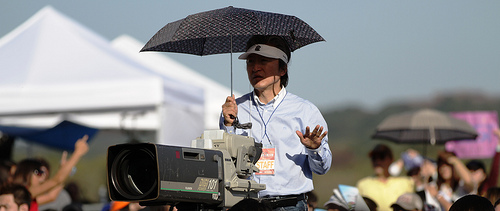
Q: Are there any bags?
A: No, there are no bags.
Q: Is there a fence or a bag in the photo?
A: No, there are no bags or fences.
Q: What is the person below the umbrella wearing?
A: The person is wearing a shirt.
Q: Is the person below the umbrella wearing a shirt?
A: Yes, the person is wearing a shirt.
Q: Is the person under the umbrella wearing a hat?
A: No, the person is wearing a shirt.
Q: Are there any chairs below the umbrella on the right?
A: No, there is a person below the umbrella.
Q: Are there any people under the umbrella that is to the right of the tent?
A: Yes, there is a person under the umbrella.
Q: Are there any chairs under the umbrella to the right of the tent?
A: No, there is a person under the umbrella.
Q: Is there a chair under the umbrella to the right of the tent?
A: No, there is a person under the umbrella.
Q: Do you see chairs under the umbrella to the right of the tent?
A: No, there is a person under the umbrella.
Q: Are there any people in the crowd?
A: Yes, there is a person in the crowd.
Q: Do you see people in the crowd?
A: Yes, there is a person in the crowd.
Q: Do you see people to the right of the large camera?
A: Yes, there is a person to the right of the camera.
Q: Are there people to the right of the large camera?
A: Yes, there is a person to the right of the camera.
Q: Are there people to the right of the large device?
A: Yes, there is a person to the right of the camera.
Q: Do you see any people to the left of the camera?
A: No, the person is to the right of the camera.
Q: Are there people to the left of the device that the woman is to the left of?
A: No, the person is to the right of the camera.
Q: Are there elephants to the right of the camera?
A: No, there is a person to the right of the camera.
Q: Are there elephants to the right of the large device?
A: No, there is a person to the right of the camera.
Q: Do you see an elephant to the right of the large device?
A: No, there is a person to the right of the camera.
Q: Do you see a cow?
A: No, there are no cows.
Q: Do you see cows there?
A: No, there are no cows.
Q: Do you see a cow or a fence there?
A: No, there are no cows or fences.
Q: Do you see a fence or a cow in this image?
A: No, there are no cows or fences.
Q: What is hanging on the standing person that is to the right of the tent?
A: The tag is hanging on the person.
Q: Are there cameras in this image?
A: Yes, there is a camera.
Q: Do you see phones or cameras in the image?
A: Yes, there is a camera.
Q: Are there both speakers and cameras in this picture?
A: No, there is a camera but no speakers.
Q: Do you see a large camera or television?
A: Yes, there is a large camera.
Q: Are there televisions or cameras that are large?
A: Yes, the camera is large.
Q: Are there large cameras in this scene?
A: Yes, there is a large camera.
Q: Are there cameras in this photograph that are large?
A: Yes, there is a camera that is large.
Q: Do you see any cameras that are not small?
A: Yes, there is a large camera.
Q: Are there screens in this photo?
A: No, there are no screens.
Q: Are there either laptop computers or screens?
A: No, there are no screens or laptop computers.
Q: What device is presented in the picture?
A: The device is a camera.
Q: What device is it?
A: The device is a camera.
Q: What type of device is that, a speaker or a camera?
A: This is a camera.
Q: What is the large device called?
A: The device is a camera.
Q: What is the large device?
A: The device is a camera.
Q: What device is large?
A: The device is a camera.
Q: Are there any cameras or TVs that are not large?
A: No, there is a camera but it is large.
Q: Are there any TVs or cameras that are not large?
A: No, there is a camera but it is large.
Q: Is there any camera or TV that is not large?
A: No, there is a camera but it is large.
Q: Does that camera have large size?
A: Yes, the camera is large.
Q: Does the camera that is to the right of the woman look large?
A: Yes, the camera is large.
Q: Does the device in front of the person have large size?
A: Yes, the camera is large.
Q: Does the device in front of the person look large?
A: Yes, the camera is large.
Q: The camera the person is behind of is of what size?
A: The camera is large.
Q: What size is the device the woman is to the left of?
A: The camera is large.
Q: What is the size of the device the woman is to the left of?
A: The camera is large.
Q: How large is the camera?
A: The camera is large.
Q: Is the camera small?
A: No, the camera is large.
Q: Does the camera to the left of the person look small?
A: No, the camera is large.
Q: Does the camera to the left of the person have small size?
A: No, the camera is large.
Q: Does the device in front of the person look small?
A: No, the camera is large.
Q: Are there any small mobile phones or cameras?
A: No, there is a camera but it is large.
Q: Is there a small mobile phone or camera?
A: No, there is a camera but it is large.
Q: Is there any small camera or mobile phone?
A: No, there is a camera but it is large.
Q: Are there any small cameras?
A: No, there is a camera but it is large.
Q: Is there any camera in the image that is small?
A: No, there is a camera but it is large.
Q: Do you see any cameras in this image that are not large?
A: No, there is a camera but it is large.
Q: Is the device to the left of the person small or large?
A: The camera is large.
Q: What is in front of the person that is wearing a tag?
A: The camera is in front of the person.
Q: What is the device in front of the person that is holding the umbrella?
A: The device is a camera.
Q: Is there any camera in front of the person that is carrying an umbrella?
A: Yes, there is a camera in front of the person.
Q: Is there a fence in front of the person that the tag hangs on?
A: No, there is a camera in front of the person.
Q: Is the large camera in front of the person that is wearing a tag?
A: Yes, the camera is in front of the person.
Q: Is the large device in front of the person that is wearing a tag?
A: Yes, the camera is in front of the person.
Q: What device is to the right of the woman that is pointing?
A: The device is a camera.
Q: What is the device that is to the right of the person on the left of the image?
A: The device is a camera.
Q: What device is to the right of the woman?
A: The device is a camera.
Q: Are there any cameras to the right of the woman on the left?
A: Yes, there is a camera to the right of the woman.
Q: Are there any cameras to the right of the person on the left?
A: Yes, there is a camera to the right of the woman.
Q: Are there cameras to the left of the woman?
A: No, the camera is to the right of the woman.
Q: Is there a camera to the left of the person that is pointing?
A: No, the camera is to the right of the woman.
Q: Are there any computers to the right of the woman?
A: No, there is a camera to the right of the woman.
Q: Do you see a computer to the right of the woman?
A: No, there is a camera to the right of the woman.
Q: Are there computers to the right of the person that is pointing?
A: No, there is a camera to the right of the woman.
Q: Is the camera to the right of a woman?
A: Yes, the camera is to the right of a woman.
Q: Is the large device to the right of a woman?
A: Yes, the camera is to the right of a woman.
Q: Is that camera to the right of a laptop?
A: No, the camera is to the right of a woman.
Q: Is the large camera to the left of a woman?
A: No, the camera is to the right of a woman.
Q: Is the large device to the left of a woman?
A: No, the camera is to the right of a woman.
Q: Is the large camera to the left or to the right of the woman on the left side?
A: The camera is to the right of the woman.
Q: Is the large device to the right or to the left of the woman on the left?
A: The camera is to the right of the woman.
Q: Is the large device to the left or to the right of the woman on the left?
A: The camera is to the right of the woman.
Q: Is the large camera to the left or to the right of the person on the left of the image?
A: The camera is to the right of the woman.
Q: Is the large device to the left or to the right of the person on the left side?
A: The camera is to the right of the woman.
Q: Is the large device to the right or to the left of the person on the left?
A: The camera is to the right of the woman.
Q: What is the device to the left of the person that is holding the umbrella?
A: The device is a camera.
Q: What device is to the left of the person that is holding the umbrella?
A: The device is a camera.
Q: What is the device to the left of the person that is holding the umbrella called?
A: The device is a camera.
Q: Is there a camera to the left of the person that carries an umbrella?
A: Yes, there is a camera to the left of the person.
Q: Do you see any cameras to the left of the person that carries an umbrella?
A: Yes, there is a camera to the left of the person.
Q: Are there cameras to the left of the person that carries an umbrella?
A: Yes, there is a camera to the left of the person.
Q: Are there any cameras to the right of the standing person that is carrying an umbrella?
A: No, the camera is to the left of the person.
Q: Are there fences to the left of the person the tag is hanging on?
A: No, there is a camera to the left of the person.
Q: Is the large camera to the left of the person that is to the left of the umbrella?
A: Yes, the camera is to the left of the person.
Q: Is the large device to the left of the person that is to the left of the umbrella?
A: Yes, the camera is to the left of the person.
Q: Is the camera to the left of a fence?
A: No, the camera is to the left of the person.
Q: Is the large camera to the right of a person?
A: No, the camera is to the left of a person.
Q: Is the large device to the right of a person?
A: No, the camera is to the left of a person.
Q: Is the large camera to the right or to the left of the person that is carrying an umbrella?
A: The camera is to the left of the person.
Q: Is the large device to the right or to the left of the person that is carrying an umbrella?
A: The camera is to the left of the person.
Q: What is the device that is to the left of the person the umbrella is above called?
A: The device is a camera.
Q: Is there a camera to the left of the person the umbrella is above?
A: Yes, there is a camera to the left of the person.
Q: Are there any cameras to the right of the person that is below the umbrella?
A: No, the camera is to the left of the person.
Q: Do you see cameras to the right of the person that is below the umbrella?
A: No, the camera is to the left of the person.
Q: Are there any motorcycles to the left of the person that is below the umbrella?
A: No, there is a camera to the left of the person.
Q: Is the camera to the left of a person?
A: Yes, the camera is to the left of a person.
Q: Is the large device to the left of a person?
A: Yes, the camera is to the left of a person.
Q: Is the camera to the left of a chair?
A: No, the camera is to the left of a person.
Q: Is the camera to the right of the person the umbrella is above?
A: No, the camera is to the left of the person.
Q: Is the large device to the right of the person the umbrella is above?
A: No, the camera is to the left of the person.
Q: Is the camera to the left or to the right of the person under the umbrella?
A: The camera is to the left of the person.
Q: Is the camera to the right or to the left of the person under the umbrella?
A: The camera is to the left of the person.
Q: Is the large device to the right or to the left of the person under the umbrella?
A: The camera is to the left of the person.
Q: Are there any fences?
A: No, there are no fences.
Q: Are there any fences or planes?
A: No, there are no fences or planes.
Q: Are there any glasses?
A: No, there are no glasses.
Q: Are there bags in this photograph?
A: No, there are no bags.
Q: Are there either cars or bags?
A: No, there are no bags or cars.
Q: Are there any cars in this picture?
A: No, there are no cars.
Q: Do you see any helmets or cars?
A: No, there are no cars or helmets.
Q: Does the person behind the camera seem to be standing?
A: Yes, the person is standing.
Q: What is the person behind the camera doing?
A: The person is standing.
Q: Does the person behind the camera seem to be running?
A: No, the person is standing.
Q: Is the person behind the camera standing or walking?
A: The person is standing.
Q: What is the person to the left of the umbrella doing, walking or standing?
A: The person is standing.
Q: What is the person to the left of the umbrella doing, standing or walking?
A: The person is standing.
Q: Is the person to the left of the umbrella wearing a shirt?
A: Yes, the person is wearing a shirt.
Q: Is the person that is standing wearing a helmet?
A: No, the person is wearing a shirt.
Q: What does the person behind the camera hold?
A: The person holds the umbrella.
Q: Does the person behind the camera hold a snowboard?
A: No, the person holds the umbrella.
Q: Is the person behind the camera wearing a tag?
A: Yes, the person is wearing a tag.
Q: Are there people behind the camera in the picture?
A: Yes, there is a person behind the camera.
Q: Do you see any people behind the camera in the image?
A: Yes, there is a person behind the camera.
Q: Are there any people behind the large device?
A: Yes, there is a person behind the camera.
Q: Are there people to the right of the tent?
A: Yes, there is a person to the right of the tent.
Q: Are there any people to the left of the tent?
A: No, the person is to the right of the tent.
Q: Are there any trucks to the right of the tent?
A: No, there is a person to the right of the tent.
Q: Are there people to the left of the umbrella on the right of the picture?
A: Yes, there is a person to the left of the umbrella.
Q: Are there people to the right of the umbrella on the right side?
A: No, the person is to the left of the umbrella.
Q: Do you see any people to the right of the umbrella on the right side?
A: No, the person is to the left of the umbrella.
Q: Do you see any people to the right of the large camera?
A: Yes, there is a person to the right of the camera.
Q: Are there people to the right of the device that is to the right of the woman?
A: Yes, there is a person to the right of the camera.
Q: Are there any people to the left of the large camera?
A: No, the person is to the right of the camera.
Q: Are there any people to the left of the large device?
A: No, the person is to the right of the camera.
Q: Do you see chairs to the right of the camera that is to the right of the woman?
A: No, there is a person to the right of the camera.